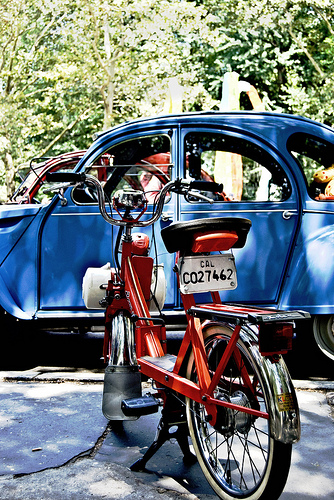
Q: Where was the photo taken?
A: It was taken at the sidewalk.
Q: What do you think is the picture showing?
A: It is showing a sidewalk.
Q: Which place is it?
A: It is a sidewalk.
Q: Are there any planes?
A: No, there are no planes.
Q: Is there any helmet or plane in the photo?
A: No, there are no airplanes or helmets.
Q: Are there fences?
A: No, there are no fences.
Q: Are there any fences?
A: No, there are no fences.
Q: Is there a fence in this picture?
A: No, there are no fences.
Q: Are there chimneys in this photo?
A: No, there are no chimneys.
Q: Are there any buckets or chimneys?
A: No, there are no chimneys or buckets.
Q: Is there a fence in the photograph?
A: No, there are no fences.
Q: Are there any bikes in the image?
A: Yes, there is a bike.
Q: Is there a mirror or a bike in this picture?
A: Yes, there is a bike.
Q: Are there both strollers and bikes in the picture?
A: No, there is a bike but no strollers.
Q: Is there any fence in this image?
A: No, there are no fences.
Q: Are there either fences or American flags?
A: No, there are no fences or American flags.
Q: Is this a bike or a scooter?
A: This is a bike.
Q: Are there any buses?
A: No, there are no buses.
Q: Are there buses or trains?
A: No, there are no buses or trains.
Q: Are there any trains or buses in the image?
A: No, there are no buses or trains.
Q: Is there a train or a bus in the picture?
A: No, there are no buses or trains.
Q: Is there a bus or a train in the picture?
A: No, there are no buses or trains.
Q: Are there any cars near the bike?
A: Yes, there is a car near the bike.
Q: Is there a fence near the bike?
A: No, there is a car near the bike.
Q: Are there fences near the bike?
A: No, there is a car near the bike.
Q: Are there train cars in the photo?
A: No, there are no train cars.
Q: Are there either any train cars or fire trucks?
A: No, there are no train cars or fire trucks.